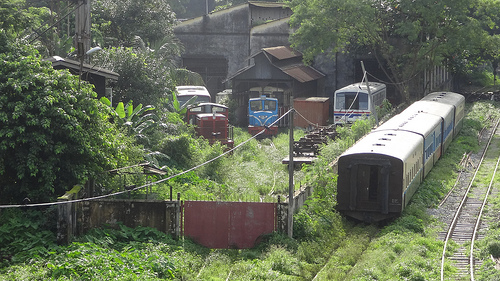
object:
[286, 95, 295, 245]
pole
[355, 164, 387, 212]
door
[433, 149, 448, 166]
ground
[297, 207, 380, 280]
rail lines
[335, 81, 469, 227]
train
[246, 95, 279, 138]
train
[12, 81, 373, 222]
power line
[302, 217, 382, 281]
grassy track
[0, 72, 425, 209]
electrical lines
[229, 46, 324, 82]
roof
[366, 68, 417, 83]
power line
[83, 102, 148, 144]
leaves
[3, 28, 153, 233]
tree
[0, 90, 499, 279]
grass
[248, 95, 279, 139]
train engine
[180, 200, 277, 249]
gate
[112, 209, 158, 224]
moss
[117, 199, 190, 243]
wall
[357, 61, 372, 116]
pole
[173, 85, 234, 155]
train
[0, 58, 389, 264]
fence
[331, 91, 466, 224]
car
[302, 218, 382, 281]
track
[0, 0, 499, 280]
train yard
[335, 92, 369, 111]
window